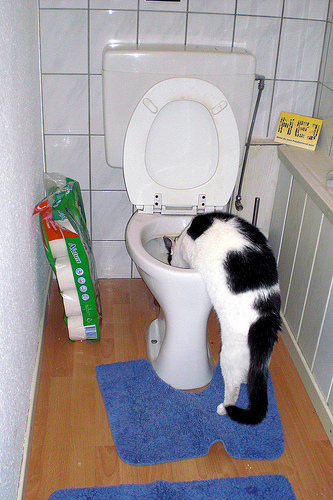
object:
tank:
[102, 43, 257, 168]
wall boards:
[266, 160, 333, 446]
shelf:
[276, 142, 333, 226]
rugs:
[48, 358, 298, 500]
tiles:
[39, 10, 327, 136]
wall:
[38, 0, 333, 278]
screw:
[151, 339, 158, 345]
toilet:
[102, 42, 256, 391]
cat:
[162, 211, 283, 427]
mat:
[49, 475, 293, 500]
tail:
[225, 315, 284, 425]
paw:
[216, 403, 228, 416]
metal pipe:
[235, 74, 265, 212]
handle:
[251, 196, 260, 230]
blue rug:
[94, 357, 286, 467]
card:
[273, 111, 323, 150]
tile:
[39, 10, 88, 75]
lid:
[102, 43, 255, 75]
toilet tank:
[102, 43, 256, 168]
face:
[168, 251, 191, 269]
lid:
[123, 75, 241, 205]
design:
[40, 366, 94, 444]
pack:
[31, 172, 102, 344]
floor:
[23, 276, 333, 498]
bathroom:
[0, 0, 332, 498]